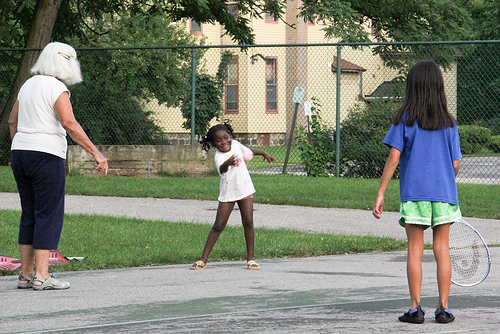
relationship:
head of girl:
[192, 114, 254, 161] [185, 114, 279, 278]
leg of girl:
[242, 181, 259, 260] [185, 114, 279, 278]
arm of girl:
[246, 142, 290, 168] [185, 114, 279, 278]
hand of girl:
[210, 150, 246, 167] [185, 114, 279, 278]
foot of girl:
[242, 239, 258, 267] [185, 114, 279, 278]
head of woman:
[34, 28, 96, 93] [10, 31, 111, 290]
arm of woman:
[45, 96, 126, 175] [10, 31, 111, 290]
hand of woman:
[90, 144, 115, 176] [10, 31, 111, 290]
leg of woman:
[25, 160, 84, 308] [10, 31, 111, 290]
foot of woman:
[31, 258, 83, 294] [10, 31, 111, 290]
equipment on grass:
[0, 239, 89, 270] [46, 225, 174, 267]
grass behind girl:
[46, 225, 174, 267] [185, 114, 279, 278]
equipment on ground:
[0, 239, 89, 270] [68, 195, 377, 318]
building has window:
[153, 6, 476, 164] [254, 52, 292, 146]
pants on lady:
[11, 152, 80, 258] [16, 17, 92, 273]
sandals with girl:
[192, 248, 214, 280] [185, 114, 279, 278]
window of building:
[254, 52, 292, 146] [153, 6, 476, 164]